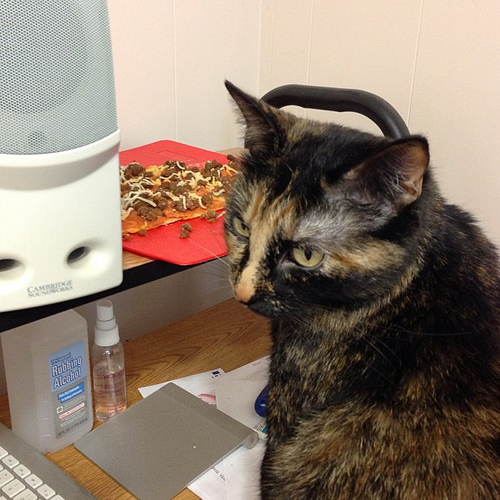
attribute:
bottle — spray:
[89, 295, 131, 424]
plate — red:
[119, 136, 227, 266]